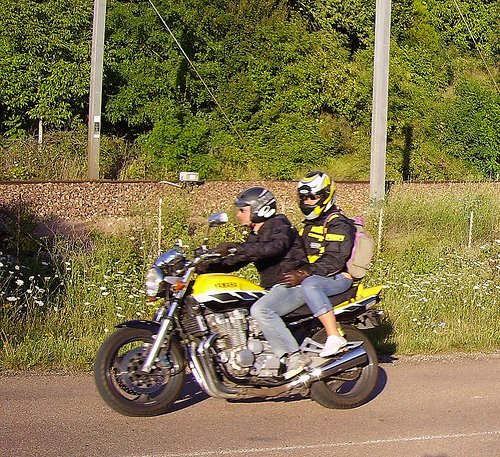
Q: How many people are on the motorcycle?
A: Two.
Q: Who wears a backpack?
A: The passenger.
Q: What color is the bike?
A: Yellow.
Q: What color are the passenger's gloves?
A: Brown.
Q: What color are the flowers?
A: White.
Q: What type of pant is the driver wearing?
A: Blue jeans.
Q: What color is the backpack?
A: Purple and grey.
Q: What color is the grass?
A: Green.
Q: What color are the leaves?
A: Green.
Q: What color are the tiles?
A: Black.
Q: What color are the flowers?
A: White.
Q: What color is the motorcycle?
A: Yellow.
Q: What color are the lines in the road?
A: White.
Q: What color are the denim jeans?
A: Blue.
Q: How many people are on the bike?
A: 2.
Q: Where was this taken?
A: On a road.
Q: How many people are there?
A: 2.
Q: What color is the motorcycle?
A: Yellow.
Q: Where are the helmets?
A: On the people's heads.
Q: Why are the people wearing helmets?
A: Safety.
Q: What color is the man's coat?
A: Black.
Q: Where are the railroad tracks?
A: Behind the road.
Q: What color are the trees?
A: Green.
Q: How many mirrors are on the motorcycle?
A: 1.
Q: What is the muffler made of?
A: Chrome.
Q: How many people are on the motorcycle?
A: Two.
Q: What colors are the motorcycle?
A: Yellow and Black.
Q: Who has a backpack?
A: The passenger.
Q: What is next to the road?
A: Flowers and tall grass.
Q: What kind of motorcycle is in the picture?
A: Yamaha.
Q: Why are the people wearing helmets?
A: For protection.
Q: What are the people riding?
A: A motorcycle.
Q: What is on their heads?
A: Helmets.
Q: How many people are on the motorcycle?
A: Two.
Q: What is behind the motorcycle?
A: Railroad tracks.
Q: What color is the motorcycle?
A: Yellow.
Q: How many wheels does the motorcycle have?
A: Two.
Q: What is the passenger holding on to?
A: The Driver's hips.